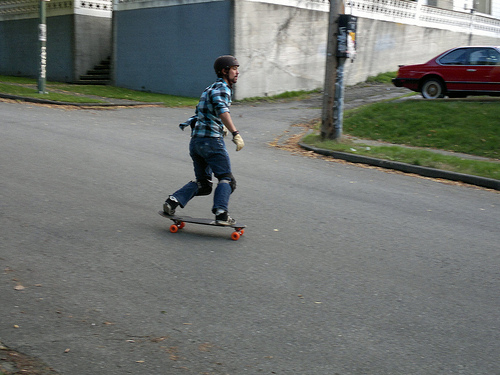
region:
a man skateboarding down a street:
[153, 40, 260, 258]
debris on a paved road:
[75, 310, 180, 373]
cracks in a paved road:
[8, 340, 55, 373]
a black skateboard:
[156, 205, 244, 227]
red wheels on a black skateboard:
[157, 217, 247, 244]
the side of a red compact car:
[381, 41, 494, 99]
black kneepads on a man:
[186, 169, 249, 201]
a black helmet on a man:
[213, 50, 240, 79]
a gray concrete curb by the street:
[323, 145, 465, 192]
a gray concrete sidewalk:
[369, 133, 487, 161]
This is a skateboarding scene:
[24, 10, 478, 365]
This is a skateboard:
[154, 200, 257, 252]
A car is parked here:
[391, 34, 498, 111]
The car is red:
[449, 64, 499, 88]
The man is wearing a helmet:
[207, 43, 247, 94]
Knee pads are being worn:
[180, 165, 244, 200]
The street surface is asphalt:
[269, 242, 440, 352]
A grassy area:
[394, 100, 491, 139]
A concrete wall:
[241, 10, 316, 86]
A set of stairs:
[74, 10, 119, 85]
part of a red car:
[392, 45, 499, 95]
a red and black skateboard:
[158, 208, 247, 239]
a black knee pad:
[217, 173, 238, 193]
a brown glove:
[231, 129, 243, 150]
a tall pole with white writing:
[37, 0, 52, 97]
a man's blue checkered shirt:
[177, 77, 234, 139]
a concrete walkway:
[347, 133, 494, 165]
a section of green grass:
[347, 99, 499, 155]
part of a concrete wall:
[113, 2, 235, 94]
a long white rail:
[258, 2, 498, 36]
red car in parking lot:
[394, 44, 499, 95]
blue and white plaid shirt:
[192, 79, 234, 141]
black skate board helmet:
[209, 53, 241, 75]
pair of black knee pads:
[201, 173, 238, 192]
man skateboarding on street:
[164, 52, 250, 234]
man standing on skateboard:
[162, 53, 258, 240]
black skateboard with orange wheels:
[159, 211, 246, 243]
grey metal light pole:
[37, 3, 49, 87]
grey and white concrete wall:
[113, 1, 239, 91]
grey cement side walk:
[346, 133, 498, 182]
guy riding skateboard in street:
[158, 55, 244, 225]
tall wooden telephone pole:
[317, 0, 342, 140]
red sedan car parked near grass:
[391, 41, 496, 93]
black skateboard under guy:
[160, 210, 245, 240]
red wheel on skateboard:
[166, 221, 176, 231]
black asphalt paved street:
[0, 90, 495, 370]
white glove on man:
[231, 131, 241, 147]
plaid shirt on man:
[177, 80, 227, 140]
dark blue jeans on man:
[170, 135, 235, 210]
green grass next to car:
[341, 95, 497, 160]